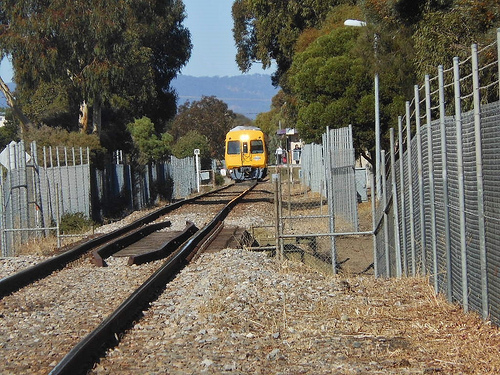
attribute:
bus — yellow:
[217, 119, 270, 183]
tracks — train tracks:
[0, 176, 251, 374]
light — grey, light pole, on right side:
[339, 14, 389, 276]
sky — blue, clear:
[178, 1, 277, 74]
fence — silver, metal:
[298, 42, 499, 320]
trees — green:
[0, 1, 197, 143]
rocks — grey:
[3, 202, 387, 372]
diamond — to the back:
[3, 138, 33, 173]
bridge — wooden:
[52, 213, 261, 264]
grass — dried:
[348, 276, 500, 374]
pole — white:
[371, 70, 382, 279]